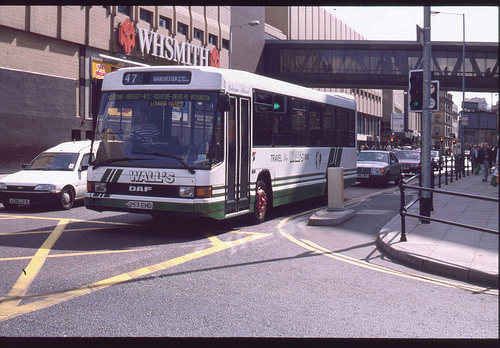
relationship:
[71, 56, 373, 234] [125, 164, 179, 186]
bus has word wall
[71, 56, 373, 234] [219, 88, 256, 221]
bus has double doors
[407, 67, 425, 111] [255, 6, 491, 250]
street light on right of bus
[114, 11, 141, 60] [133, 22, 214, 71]
red design with business name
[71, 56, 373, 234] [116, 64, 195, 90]
bus has a marquee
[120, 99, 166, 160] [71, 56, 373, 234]
man driving bus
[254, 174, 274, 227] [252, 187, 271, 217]
bus wheel has red hub cap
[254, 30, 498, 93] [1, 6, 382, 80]
bridge connects buildings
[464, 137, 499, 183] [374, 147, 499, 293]
people walks on sidewalk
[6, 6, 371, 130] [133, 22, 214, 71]
building has white letters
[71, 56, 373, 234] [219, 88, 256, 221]
bus has glass door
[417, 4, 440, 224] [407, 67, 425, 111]
pole has street light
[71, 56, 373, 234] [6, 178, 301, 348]
bus driving down  street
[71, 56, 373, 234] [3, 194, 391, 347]
bus in intersection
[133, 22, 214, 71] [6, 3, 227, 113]
sign for bookstore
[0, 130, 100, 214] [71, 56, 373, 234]
white vehicle beside bus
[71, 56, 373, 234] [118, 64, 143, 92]
bus number 47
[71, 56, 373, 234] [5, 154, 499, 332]
bus on city street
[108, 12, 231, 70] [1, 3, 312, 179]
sign of business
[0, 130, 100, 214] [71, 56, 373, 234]
white car next to bus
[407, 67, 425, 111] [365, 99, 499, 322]
street light on corner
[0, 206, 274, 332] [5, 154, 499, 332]
yellow lines on street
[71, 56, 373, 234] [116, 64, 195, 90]
bus has location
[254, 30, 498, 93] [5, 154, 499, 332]
overhead walkway above street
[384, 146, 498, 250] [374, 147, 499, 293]
railing along sidewalk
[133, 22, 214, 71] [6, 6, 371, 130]
name outside wall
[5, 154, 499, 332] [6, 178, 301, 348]
street has yellow markings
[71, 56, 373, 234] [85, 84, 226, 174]
bus has front window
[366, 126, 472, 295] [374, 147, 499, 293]
barrier at sidewalk